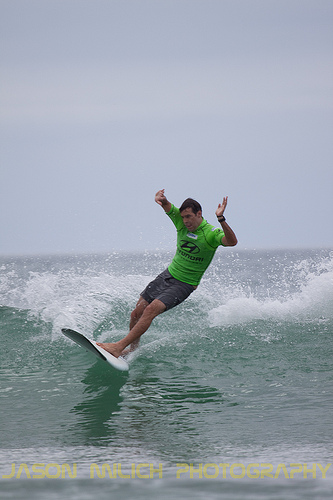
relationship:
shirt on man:
[166, 203, 224, 285] [96, 189, 238, 357]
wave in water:
[1, 253, 332, 346] [3, 248, 330, 498]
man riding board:
[96, 189, 238, 357] [60, 326, 130, 372]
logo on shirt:
[177, 236, 205, 263] [166, 203, 224, 285]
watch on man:
[218, 216, 227, 224] [96, 189, 238, 357]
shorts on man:
[139, 269, 196, 309] [96, 189, 238, 357]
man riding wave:
[96, 189, 238, 357] [1, 253, 332, 346]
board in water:
[60, 326, 130, 372] [3, 248, 330, 498]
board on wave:
[60, 326, 130, 372] [1, 253, 332, 346]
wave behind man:
[1, 253, 332, 346] [96, 189, 238, 357]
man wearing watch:
[96, 189, 238, 357] [218, 216, 227, 224]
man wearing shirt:
[96, 189, 238, 357] [166, 203, 224, 285]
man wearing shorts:
[96, 189, 238, 357] [139, 269, 196, 309]